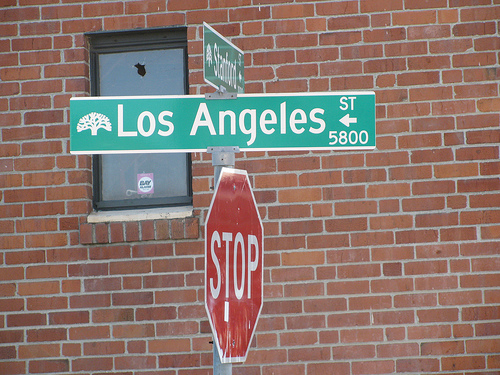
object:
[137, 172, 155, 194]
sticker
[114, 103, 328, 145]
name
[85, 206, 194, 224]
ledge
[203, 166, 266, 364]
sign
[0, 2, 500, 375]
building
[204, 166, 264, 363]
stop sign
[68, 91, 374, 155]
sign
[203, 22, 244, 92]
sign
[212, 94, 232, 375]
pole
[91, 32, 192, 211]
window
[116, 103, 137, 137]
letter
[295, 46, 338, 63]
brick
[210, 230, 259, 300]
word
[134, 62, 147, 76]
hole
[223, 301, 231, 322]
sticker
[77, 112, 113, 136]
tree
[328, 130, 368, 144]
street number